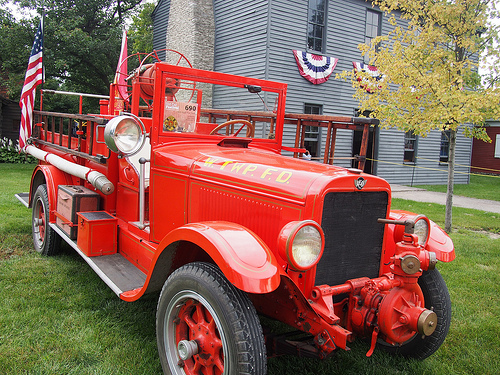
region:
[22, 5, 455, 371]
old style red firetruck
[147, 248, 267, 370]
front wheel of firetruck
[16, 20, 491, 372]
bright red firetruck on grass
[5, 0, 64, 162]
united states flag on truck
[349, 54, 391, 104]
red, white, and blue cloth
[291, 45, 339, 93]
red, white, and blue cloth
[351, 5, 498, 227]
small green tree next to truck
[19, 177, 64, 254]
back wheel of firetruck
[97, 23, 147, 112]
red flag on fire truck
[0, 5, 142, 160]
two flags in back of truck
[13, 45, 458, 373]
an old red fire truck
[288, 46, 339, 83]
red, white and blue banner on the building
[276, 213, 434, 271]
red and white headlights on the truck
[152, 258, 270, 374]
black tire on the red truck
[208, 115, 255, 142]
red steering wheel in the truck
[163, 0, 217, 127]
gray fire place on the outside of the building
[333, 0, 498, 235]
tree by the truck and building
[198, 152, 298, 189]
yellow letters on the red truck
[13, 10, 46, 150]
red, white and blue flag on the back of the truck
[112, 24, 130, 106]
red flag on the back of the truck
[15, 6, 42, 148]
American flag hanging outside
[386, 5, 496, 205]
planted tree standing outside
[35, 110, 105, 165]
ladder hanging on side of truck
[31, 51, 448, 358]
old red fire truck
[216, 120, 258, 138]
red steering wheel inside of truck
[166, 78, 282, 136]
windshield of the truck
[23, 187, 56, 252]
black back tire on right side of truck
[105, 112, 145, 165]
light on side of truck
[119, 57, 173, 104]
fire hose on truck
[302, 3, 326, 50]
window on the building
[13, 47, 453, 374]
old fashioned red fire truck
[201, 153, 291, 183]
yellow letters on the red fire truck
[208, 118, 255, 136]
steering wheel on the fire truck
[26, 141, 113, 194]
fire hose attached to the side of the truck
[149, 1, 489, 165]
two story blue house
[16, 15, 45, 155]
American flag on the back of the truck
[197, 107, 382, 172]
red letter on the side of the truck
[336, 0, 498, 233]
small tree in the yard in front of blue house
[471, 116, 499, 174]
building bside the blue house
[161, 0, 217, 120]
stone chimney on the house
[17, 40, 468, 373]
red antique fire truck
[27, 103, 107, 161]
a ladder located on truck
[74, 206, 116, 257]
a red box with a black lid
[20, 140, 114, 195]
A white hose with red mounts to fire truck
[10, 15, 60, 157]
the American Flag on truck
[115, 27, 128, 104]
A red flag on truck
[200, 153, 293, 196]
yellow lettering that says W.TWP.F.D.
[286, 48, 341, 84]
red, white, and blue decoration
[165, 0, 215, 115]
a brick chimney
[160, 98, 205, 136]
a plaque with lettering 690 and a safety ring